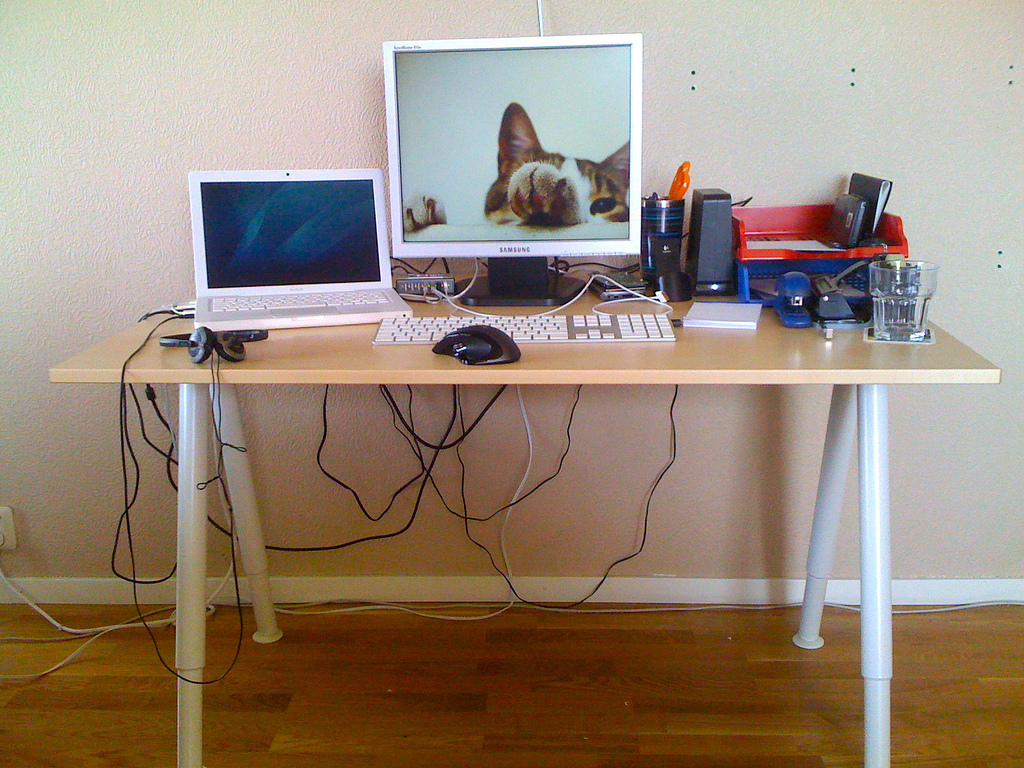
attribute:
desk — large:
[52, 307, 1012, 765]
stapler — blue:
[767, 270, 822, 337]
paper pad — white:
[675, 294, 768, 340]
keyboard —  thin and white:
[370, 291, 686, 367]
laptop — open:
[184, 144, 394, 382]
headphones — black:
[143, 313, 269, 398]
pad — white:
[672, 287, 768, 339]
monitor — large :
[361, 70, 699, 278]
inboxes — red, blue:
[699, 161, 959, 332]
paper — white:
[673, 281, 766, 351]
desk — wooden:
[86, 311, 974, 424]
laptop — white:
[177, 263, 433, 384]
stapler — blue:
[747, 256, 817, 356]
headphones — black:
[138, 319, 290, 376]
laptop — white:
[184, 163, 414, 338]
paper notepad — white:
[679, 299, 766, 334]